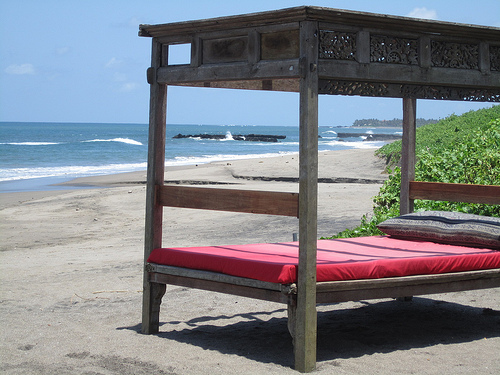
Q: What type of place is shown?
A: It is a beach.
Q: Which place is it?
A: It is a beach.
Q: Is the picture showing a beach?
A: Yes, it is showing a beach.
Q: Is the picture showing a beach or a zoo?
A: It is showing a beach.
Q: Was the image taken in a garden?
A: No, the picture was taken in a beach.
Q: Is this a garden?
A: No, it is a beach.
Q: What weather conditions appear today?
A: It is clear.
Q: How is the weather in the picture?
A: It is clear.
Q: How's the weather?
A: It is clear.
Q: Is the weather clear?
A: Yes, it is clear.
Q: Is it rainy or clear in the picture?
A: It is clear.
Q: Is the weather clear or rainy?
A: It is clear.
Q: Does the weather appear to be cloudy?
A: No, it is clear.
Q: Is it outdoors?
A: Yes, it is outdoors.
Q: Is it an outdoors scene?
A: Yes, it is outdoors.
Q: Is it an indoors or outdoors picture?
A: It is outdoors.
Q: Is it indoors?
A: No, it is outdoors.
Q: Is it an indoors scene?
A: No, it is outdoors.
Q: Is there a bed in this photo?
A: Yes, there is a bed.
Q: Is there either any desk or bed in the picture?
A: Yes, there is a bed.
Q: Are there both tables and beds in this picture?
A: No, there is a bed but no tables.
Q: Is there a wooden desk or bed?
A: Yes, there is a wood bed.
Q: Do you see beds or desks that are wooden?
A: Yes, the bed is wooden.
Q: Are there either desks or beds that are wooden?
A: Yes, the bed is wooden.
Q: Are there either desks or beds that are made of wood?
A: Yes, the bed is made of wood.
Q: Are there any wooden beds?
A: Yes, there is a wood bed.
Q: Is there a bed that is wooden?
A: Yes, there is a bed that is wooden.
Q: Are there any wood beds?
A: Yes, there is a bed that is made of wood.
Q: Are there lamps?
A: No, there are no lamps.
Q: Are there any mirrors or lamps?
A: No, there are no lamps or mirrors.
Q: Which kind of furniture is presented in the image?
A: The furniture is a bed.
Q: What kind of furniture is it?
A: The piece of furniture is a bed.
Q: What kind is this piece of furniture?
A: This is a bed.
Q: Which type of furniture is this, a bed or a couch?
A: This is a bed.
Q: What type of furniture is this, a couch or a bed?
A: This is a bed.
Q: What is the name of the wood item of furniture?
A: The piece of furniture is a bed.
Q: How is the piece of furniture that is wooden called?
A: The piece of furniture is a bed.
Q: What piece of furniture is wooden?
A: The piece of furniture is a bed.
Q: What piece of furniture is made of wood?
A: The piece of furniture is a bed.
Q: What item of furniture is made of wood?
A: The piece of furniture is a bed.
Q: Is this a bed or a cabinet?
A: This is a bed.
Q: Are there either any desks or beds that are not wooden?
A: No, there is a bed but it is wooden.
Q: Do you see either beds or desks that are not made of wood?
A: No, there is a bed but it is made of wood.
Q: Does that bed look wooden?
A: Yes, the bed is wooden.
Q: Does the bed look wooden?
A: Yes, the bed is wooden.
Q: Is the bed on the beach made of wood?
A: Yes, the bed is made of wood.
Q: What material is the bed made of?
A: The bed is made of wood.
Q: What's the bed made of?
A: The bed is made of wood.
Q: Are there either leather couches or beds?
A: No, there is a bed but it is wooden.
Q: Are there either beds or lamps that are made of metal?
A: No, there is a bed but it is made of wood.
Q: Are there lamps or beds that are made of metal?
A: No, there is a bed but it is made of wood.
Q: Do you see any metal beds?
A: No, there is a bed but it is made of wood.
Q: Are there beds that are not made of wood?
A: No, there is a bed but it is made of wood.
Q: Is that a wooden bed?
A: Yes, that is a wooden bed.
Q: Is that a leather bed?
A: No, that is a wooden bed.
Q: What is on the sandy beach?
A: The bed is on the beach.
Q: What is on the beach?
A: The bed is on the beach.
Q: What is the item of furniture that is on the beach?
A: The piece of furniture is a bed.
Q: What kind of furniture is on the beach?
A: The piece of furniture is a bed.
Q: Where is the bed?
A: The bed is on the beach.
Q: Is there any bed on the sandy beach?
A: Yes, there is a bed on the beach.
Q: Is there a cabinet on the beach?
A: No, there is a bed on the beach.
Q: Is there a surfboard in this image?
A: No, there are no surfboards.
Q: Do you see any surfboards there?
A: No, there are no surfboards.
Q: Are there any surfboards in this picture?
A: No, there are no surfboards.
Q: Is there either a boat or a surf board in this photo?
A: No, there are no surfboards or boats.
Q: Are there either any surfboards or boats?
A: No, there are no surfboards or boats.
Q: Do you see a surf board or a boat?
A: No, there are no surfboards or boats.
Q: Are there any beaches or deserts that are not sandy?
A: No, there is a beach but it is sandy.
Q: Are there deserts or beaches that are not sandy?
A: No, there is a beach but it is sandy.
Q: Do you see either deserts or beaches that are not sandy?
A: No, there is a beach but it is sandy.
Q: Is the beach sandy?
A: Yes, the beach is sandy.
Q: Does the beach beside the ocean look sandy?
A: Yes, the beach is sandy.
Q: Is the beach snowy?
A: No, the beach is sandy.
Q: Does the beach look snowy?
A: No, the beach is sandy.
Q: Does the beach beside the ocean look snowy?
A: No, the beach is sandy.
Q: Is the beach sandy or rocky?
A: The beach is sandy.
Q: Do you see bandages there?
A: No, there are no bandages.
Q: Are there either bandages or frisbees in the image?
A: No, there are no bandages or frisbees.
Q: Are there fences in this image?
A: No, there are no fences.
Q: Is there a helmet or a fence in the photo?
A: No, there are no fences or helmets.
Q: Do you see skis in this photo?
A: No, there are no skis.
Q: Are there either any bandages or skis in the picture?
A: No, there are no skis or bandages.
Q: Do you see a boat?
A: No, there are no boats.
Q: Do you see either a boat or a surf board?
A: No, there are no boats or surfboards.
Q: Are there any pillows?
A: Yes, there is a pillow.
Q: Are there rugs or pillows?
A: Yes, there is a pillow.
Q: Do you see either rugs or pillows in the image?
A: Yes, there is a pillow.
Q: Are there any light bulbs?
A: No, there are no light bulbs.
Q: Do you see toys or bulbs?
A: No, there are no bulbs or toys.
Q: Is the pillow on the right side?
A: Yes, the pillow is on the right of the image.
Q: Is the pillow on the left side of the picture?
A: No, the pillow is on the right of the image.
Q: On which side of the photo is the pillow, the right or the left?
A: The pillow is on the right of the image.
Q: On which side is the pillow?
A: The pillow is on the right of the image.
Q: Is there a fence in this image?
A: No, there are no fences.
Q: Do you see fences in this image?
A: No, there are no fences.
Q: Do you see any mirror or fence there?
A: No, there are no fences or mirrors.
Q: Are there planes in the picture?
A: No, there are no planes.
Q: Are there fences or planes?
A: No, there are no planes or fences.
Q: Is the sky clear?
A: Yes, the sky is clear.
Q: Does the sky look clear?
A: Yes, the sky is clear.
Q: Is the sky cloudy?
A: No, the sky is clear.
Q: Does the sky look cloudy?
A: No, the sky is clear.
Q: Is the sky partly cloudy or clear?
A: The sky is clear.